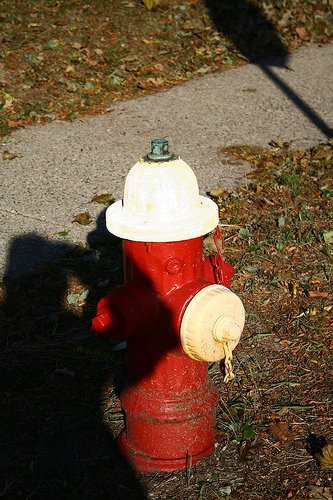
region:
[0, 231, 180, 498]
a persons shadow on the grass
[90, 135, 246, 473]
a red and white fire hydrant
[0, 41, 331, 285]
a gray sidewalk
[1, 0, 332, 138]
a patch of leaf covered grass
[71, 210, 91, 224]
a leaf on a sidewalk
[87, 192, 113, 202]
a leaf on a sidewalk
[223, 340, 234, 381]
a white chain on a fire hydrant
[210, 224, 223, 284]
a red chain on a hydrant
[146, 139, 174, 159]
a blot atop a fire hydrant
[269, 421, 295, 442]
a leaf in the grass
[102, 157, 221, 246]
White top of fire hydrant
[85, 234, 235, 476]
Red bottom of fire hydrant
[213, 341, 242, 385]
White chain on fire hydrant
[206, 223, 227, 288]
Red chain on fire hydrant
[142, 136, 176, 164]
Bolt on top of fire hydrant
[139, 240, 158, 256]
Bolt and screw on fire hydrant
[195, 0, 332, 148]
Black shadow on ground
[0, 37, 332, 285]
Gray gravel path on ground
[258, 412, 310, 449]
Brown leaf on ground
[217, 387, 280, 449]
Green grass on ground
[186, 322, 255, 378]
white chain hanging from hydrant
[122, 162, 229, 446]
fire hydrant is red and white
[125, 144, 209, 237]
fire hydrant with white cap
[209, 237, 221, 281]
red chain hanging from hydrant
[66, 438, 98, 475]
shadow behind red hydrant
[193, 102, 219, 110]
gray spotted sidewalk behind hydrant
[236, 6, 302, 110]
shadow of stop sign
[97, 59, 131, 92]
green leaves on ground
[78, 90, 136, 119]
red and brown debris on ground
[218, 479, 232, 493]
small rock by hydrant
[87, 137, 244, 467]
red and white fire hydrant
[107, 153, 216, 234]
white top of fire hydrant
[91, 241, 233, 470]
red body of fire hydrant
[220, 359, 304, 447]
grass growing beside fire hydrant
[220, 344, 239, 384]
white chain hanging off fire hydrant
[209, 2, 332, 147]
shadow from street sign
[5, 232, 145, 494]
shadow of person taking picture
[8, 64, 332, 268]
sidewalk behind fire hydrant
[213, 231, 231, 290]
red chain hanging from fire hydrant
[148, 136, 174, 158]
bolt on top of fire hydrant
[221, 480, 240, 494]
part of a stone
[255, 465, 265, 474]
part of a ground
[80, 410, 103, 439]
part of a shade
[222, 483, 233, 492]
part of a stone